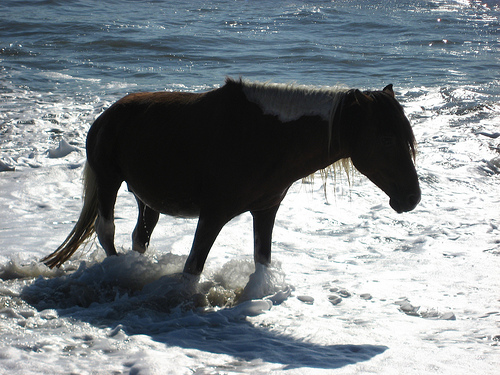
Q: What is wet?
A: A horse.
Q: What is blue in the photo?
A: The ocean.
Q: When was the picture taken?
A: During the day.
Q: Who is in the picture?
A: No-one.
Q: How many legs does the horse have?
A: Four.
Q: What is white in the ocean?
A: Foam.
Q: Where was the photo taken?
A: At the beach.